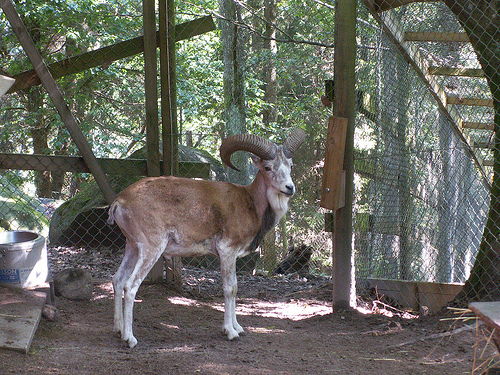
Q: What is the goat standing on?
A: Dirt.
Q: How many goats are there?
A: One.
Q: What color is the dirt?
A: Brown.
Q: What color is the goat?
A: Brown and white.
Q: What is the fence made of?
A: Chain link.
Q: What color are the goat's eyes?
A: Black.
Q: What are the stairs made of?
A: Wood.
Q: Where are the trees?
A: Behind the fence.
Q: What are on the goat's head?
A: Horns.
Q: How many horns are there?
A: Two.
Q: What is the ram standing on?
A: Dirt.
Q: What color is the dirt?
A: Brown.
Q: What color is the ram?
A: Brown.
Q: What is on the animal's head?
A: Horns'.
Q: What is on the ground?
A: Dirt.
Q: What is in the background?
A: Trees.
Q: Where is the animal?
A: Enclosure.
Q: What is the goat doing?
A: Standing.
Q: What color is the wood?
A: Brown.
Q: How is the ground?
A: Dirty.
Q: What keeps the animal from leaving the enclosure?
A: The fence.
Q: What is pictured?
A: Ram.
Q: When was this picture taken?
A: Daytime.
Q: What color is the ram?
A: Brown.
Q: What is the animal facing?
A: Camera.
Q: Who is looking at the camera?
A: The ram.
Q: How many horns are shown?
A: 2.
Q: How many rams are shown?
A: 1.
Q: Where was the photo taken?
A: In a goat enclosure.